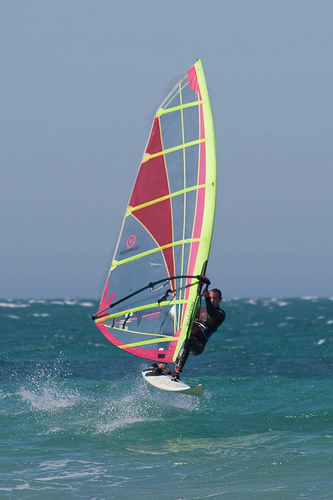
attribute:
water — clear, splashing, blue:
[25, 363, 83, 440]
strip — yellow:
[144, 132, 209, 155]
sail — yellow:
[125, 90, 212, 359]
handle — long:
[150, 274, 195, 299]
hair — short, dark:
[214, 290, 227, 304]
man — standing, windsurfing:
[193, 288, 221, 376]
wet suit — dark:
[184, 312, 220, 357]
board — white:
[145, 379, 198, 395]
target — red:
[114, 235, 147, 251]